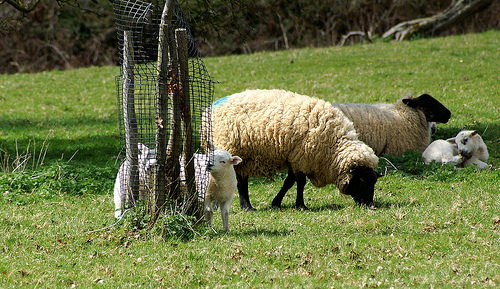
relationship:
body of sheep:
[209, 90, 341, 221] [198, 86, 380, 208]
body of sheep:
[341, 83, 429, 173] [334, 90, 454, 157]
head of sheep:
[398, 82, 458, 121] [313, 82, 468, 161]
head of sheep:
[205, 142, 242, 173] [177, 140, 242, 235]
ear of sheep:
[196, 135, 208, 163] [177, 144, 245, 237]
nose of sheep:
[204, 160, 220, 170] [182, 137, 281, 202]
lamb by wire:
[186, 147, 244, 236] [107, 2, 219, 232]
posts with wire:
[118, 1, 191, 219] [113, 0, 215, 235]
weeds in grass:
[1, 135, 113, 197] [3, 162, 498, 287]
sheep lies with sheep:
[334, 90, 454, 157] [420, 130, 489, 172]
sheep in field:
[206, 86, 386, 213] [380, 250, 499, 272]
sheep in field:
[329, 93, 454, 164] [380, 250, 499, 272]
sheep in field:
[424, 127, 494, 174] [380, 250, 499, 272]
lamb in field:
[112, 148, 243, 233] [380, 250, 499, 272]